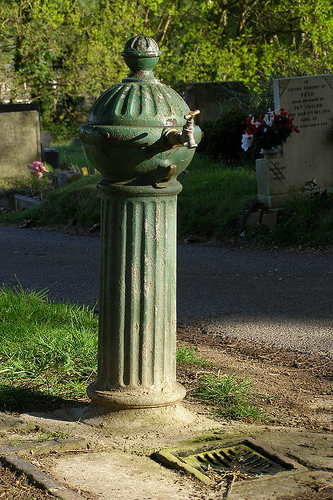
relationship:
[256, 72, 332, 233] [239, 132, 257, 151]
grave with flower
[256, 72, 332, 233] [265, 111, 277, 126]
grave with flower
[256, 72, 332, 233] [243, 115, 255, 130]
grave with flower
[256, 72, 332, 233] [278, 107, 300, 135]
grave with flower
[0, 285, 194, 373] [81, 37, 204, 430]
grass next to monument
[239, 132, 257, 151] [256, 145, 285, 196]
flower in vase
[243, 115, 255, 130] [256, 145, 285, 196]
flower in vase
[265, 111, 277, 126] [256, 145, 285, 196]
flower in vase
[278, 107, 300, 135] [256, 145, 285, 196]
flower in vase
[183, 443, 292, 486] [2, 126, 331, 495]
drain on ground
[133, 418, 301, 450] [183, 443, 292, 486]
dirt above drain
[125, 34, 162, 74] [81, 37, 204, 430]
structure on monument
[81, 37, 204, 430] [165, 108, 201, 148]
monument with spout